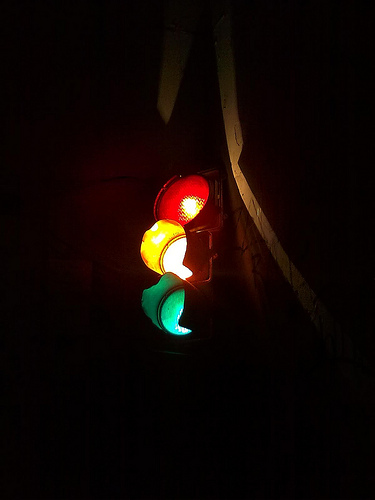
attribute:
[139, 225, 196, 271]
light — yellow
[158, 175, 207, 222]
shield — plastic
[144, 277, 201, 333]
light — green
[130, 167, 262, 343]
light — green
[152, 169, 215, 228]
light — red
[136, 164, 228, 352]
traffic light — green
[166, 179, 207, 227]
light — red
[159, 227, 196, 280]
light — orange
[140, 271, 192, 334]
round shield — plastic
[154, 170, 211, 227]
traffic light — red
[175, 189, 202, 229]
center — red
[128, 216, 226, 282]
light — orange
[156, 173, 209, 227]
circle — green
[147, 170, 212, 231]
traffic light — square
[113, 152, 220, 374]
light — orange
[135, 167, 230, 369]
traffic light — lit